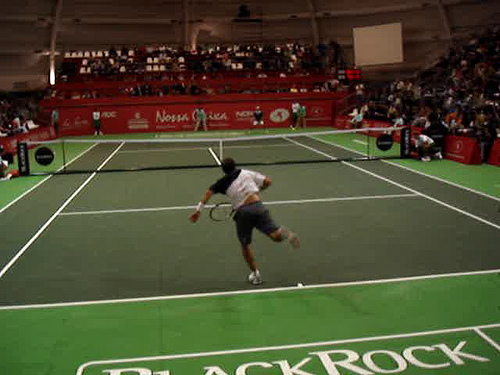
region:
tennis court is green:
[49, 190, 206, 319]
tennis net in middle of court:
[19, 127, 442, 174]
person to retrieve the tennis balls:
[408, 128, 439, 177]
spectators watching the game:
[398, 57, 499, 143]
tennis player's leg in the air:
[211, 162, 355, 303]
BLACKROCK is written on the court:
[92, 361, 499, 373]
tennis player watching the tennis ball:
[247, 107, 273, 137]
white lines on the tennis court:
[113, 128, 373, 224]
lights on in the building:
[68, 21, 343, 91]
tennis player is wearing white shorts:
[242, 104, 289, 149]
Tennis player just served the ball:
[188, 153, 303, 285]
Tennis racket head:
[208, 202, 230, 227]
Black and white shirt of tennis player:
[207, 167, 265, 212]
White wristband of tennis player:
[192, 197, 209, 215]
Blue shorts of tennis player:
[233, 200, 275, 248]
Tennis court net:
[26, 125, 416, 170]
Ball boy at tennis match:
[410, 128, 442, 161]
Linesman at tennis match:
[190, 105, 210, 128]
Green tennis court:
[0, 128, 498, 308]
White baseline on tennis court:
[1, 267, 499, 312]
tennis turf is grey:
[67, 188, 183, 338]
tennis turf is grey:
[68, 212, 168, 262]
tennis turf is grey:
[302, 181, 454, 318]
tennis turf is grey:
[258, 192, 387, 260]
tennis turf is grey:
[77, 160, 234, 300]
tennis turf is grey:
[230, 136, 404, 303]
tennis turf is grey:
[109, 117, 394, 354]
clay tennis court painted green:
[0, 109, 499, 319]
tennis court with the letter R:
[291, 329, 366, 374]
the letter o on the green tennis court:
[360, 339, 411, 374]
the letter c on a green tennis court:
[396, 338, 451, 368]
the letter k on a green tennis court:
[427, 335, 487, 370]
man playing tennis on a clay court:
[125, 137, 326, 308]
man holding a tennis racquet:
[176, 148, 298, 294]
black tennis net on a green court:
[0, 123, 423, 181]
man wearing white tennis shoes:
[183, 199, 333, 300]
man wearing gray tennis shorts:
[191, 194, 327, 290]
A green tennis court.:
[0, 88, 499, 373]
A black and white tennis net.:
[11, 113, 413, 179]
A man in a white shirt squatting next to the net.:
[405, 127, 445, 162]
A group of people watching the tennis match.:
[3, 10, 499, 160]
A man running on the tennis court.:
[181, 149, 306, 306]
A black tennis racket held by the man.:
[201, 198, 241, 230]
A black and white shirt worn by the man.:
[194, 164, 274, 221]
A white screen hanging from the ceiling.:
[340, 13, 416, 82]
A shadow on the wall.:
[186, 20, 234, 58]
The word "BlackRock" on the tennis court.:
[60, 327, 499, 374]